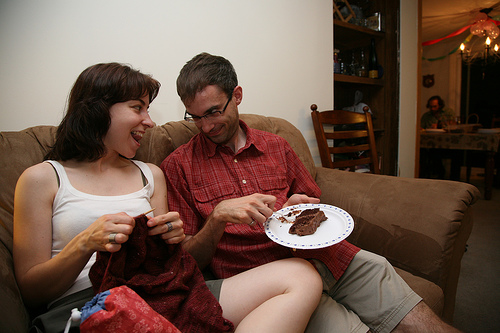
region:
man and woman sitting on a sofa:
[7, 50, 399, 331]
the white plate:
[264, 199, 356, 246]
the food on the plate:
[287, 205, 324, 236]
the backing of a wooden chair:
[308, 99, 386, 179]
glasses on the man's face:
[175, 94, 234, 124]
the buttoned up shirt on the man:
[167, 125, 360, 273]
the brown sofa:
[3, 100, 478, 331]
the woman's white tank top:
[25, 147, 156, 284]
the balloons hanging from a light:
[464, 8, 499, 42]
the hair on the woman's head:
[40, 58, 141, 167]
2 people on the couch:
[6, 15, 458, 332]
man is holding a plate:
[189, 132, 354, 278]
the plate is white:
[239, 177, 361, 270]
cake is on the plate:
[270, 190, 334, 255]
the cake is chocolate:
[277, 192, 335, 233]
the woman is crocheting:
[43, 165, 239, 309]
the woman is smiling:
[50, 47, 157, 163]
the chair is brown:
[291, 81, 400, 170]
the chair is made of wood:
[299, 92, 393, 172]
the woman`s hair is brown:
[30, 51, 170, 172]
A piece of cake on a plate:
[262, 200, 359, 250]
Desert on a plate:
[264, 196, 354, 251]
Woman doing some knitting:
[14, 60, 325, 332]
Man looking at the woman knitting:
[157, 49, 476, 331]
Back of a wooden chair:
[308, 101, 382, 173]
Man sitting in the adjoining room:
[420, 93, 458, 126]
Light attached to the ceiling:
[454, 5, 499, 50]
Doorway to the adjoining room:
[415, 0, 498, 207]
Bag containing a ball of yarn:
[59, 283, 179, 331]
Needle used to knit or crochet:
[130, 207, 153, 219]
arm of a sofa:
[366, 170, 481, 250]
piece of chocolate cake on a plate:
[275, 201, 345, 237]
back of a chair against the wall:
[307, 90, 384, 170]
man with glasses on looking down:
[167, 50, 262, 151]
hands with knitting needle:
[90, 204, 193, 263]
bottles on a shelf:
[330, 20, 386, 76]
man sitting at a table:
[415, 87, 462, 187]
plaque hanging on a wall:
[417, 67, 440, 93]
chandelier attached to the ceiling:
[451, 6, 496, 56]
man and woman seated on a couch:
[20, 51, 437, 316]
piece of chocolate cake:
[283, 208, 328, 235]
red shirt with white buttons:
[161, 136, 361, 271]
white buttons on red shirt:
[226, 154, 253, 189]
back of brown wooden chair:
[308, 103, 381, 174]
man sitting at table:
[424, 96, 459, 133]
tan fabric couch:
[2, 113, 485, 328]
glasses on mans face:
[176, 96, 243, 123]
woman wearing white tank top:
[13, 61, 323, 331]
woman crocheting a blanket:
[13, 61, 328, 330]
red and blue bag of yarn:
[59, 285, 198, 331]